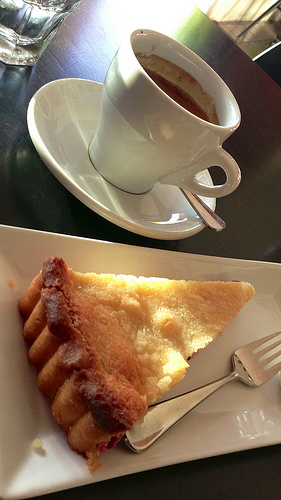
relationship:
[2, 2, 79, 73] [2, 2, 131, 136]
glass in corner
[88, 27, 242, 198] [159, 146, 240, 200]
cup has a handle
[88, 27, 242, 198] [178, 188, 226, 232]
cup by a teaspoon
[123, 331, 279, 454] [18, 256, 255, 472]
fork by a pie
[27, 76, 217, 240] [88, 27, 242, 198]
plate under a cup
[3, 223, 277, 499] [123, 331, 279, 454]
plate has a fork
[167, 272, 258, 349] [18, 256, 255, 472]
piece of pie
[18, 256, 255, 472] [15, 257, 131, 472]
pastry has a crust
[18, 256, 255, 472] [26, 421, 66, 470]
pie has crumbs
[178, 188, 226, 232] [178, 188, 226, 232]
teaspoon has a teaspoon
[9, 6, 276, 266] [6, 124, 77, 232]
table has a reflection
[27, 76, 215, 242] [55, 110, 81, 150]
plate has a reflection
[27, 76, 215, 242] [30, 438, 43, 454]
plate has a crumb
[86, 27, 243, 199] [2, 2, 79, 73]
cup by a glass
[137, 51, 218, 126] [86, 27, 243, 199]
chocolate in a cup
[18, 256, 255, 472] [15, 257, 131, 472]
pie has a crust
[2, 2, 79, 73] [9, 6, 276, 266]
glass on table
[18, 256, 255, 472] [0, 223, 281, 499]
pie on plate